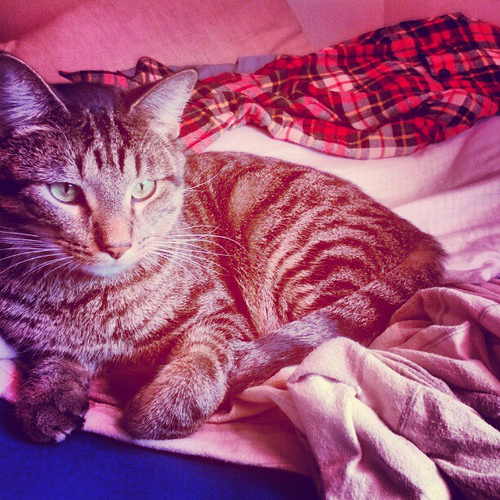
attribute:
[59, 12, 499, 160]
blanket — patterned, colored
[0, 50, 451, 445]
cat — patterned, brown, lying, colored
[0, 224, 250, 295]
whiskers — white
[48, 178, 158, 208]
eyes — green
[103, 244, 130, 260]
nose — pink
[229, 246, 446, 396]
tail — curled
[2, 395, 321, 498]
blanket — blue